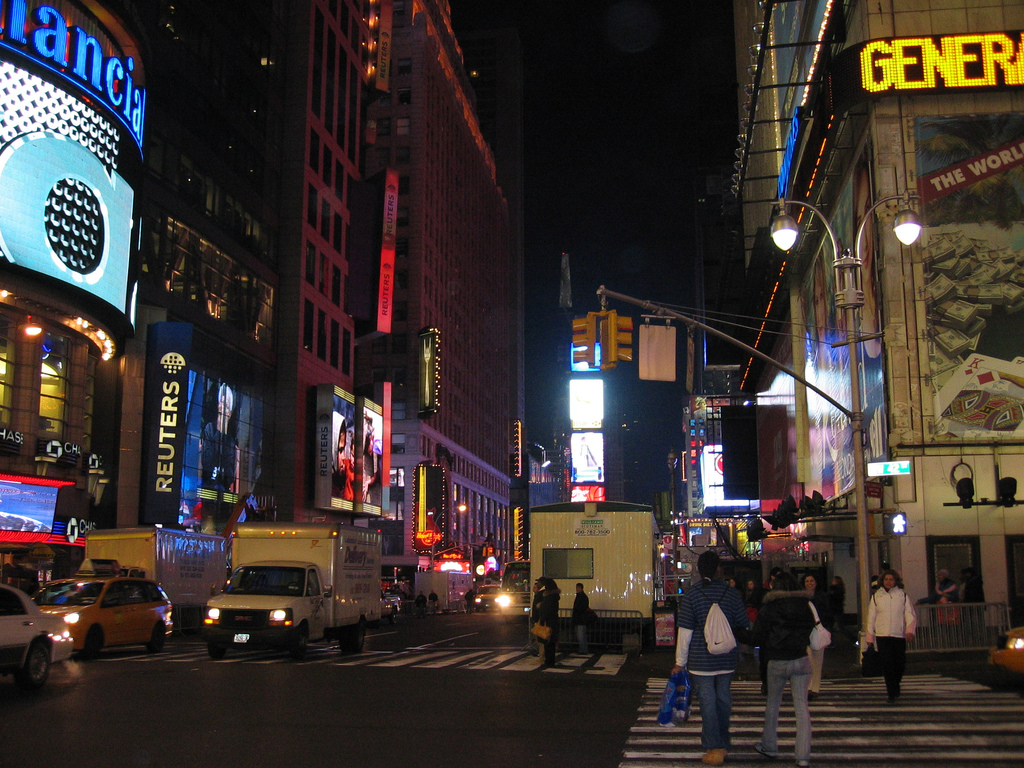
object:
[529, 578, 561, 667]
person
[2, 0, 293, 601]
building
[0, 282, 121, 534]
wall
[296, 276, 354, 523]
wall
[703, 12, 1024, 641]
building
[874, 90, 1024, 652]
wall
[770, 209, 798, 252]
light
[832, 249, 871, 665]
pole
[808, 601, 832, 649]
bag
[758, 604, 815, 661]
shoulder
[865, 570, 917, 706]
person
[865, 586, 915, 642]
coat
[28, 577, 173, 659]
car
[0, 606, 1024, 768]
street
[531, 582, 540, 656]
person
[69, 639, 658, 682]
crosswalk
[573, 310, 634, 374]
signal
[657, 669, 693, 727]
bag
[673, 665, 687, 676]
hand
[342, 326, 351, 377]
window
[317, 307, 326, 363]
window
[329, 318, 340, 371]
window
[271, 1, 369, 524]
building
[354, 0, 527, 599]
building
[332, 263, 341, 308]
window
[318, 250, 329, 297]
window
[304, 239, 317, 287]
window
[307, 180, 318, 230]
window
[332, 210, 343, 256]
window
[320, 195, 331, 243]
window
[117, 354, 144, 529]
wall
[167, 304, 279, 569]
wall